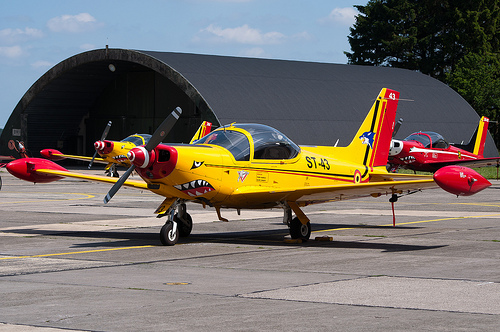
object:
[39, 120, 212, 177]
flights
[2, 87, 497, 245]
flight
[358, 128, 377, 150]
logo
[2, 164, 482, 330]
runway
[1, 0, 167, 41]
sky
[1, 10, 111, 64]
clouds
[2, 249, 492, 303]
pavement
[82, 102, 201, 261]
angle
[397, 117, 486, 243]
color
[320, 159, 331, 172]
number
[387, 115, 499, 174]
plane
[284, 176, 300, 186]
yellow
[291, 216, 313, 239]
back wheel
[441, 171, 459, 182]
red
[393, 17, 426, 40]
dark green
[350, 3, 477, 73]
trees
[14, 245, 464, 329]
ground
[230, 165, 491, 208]
wing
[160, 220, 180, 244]
front wheel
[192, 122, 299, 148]
roof